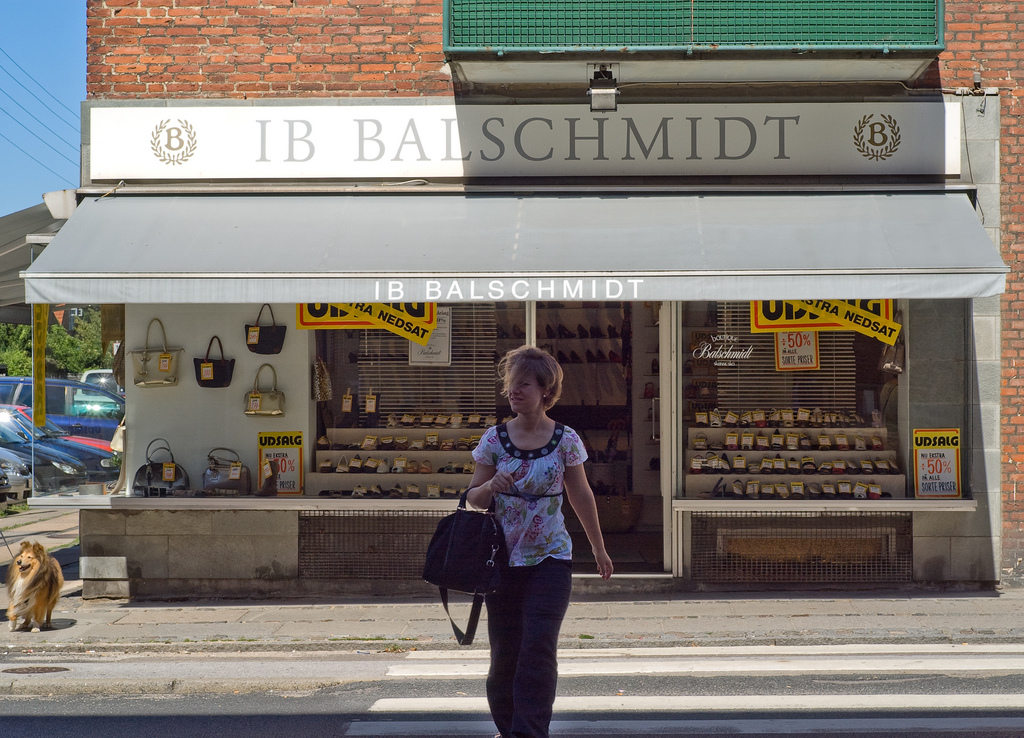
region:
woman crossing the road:
[425, 338, 628, 735]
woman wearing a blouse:
[456, 416, 606, 576]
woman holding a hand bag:
[424, 480, 510, 645]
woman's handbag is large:
[405, 479, 516, 658]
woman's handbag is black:
[405, 479, 522, 656]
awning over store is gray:
[14, 175, 1014, 308]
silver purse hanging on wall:
[120, 312, 191, 392]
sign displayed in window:
[904, 423, 965, 503]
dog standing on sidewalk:
[4, 530, 65, 641]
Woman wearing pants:
[454, 545, 587, 735]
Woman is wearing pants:
[457, 554, 578, 735]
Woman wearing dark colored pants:
[476, 555, 588, 734]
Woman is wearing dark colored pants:
[479, 550, 581, 734]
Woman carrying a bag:
[409, 471, 530, 650]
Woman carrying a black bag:
[411, 479, 517, 650]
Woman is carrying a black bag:
[408, 475, 516, 652]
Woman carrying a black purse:
[418, 476, 514, 647]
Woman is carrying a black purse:
[415, 472, 507, 651]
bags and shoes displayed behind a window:
[124, 305, 523, 498]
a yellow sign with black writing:
[909, 423, 963, 500]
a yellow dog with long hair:
[0, 536, 62, 631]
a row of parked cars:
[0, 371, 125, 512]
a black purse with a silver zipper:
[424, 486, 505, 645]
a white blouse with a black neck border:
[468, 422, 587, 563]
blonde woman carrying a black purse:
[421, 350, 609, 733]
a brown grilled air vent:
[295, 504, 455, 587]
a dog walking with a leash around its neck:
[1, 530, 65, 636]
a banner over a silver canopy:
[24, 97, 1007, 306]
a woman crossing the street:
[414, 344, 610, 734]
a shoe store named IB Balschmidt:
[78, 99, 1003, 612]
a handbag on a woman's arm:
[420, 488, 509, 647]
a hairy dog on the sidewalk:
[6, 542, 63, 632]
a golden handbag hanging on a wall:
[126, 315, 181, 386]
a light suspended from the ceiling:
[581, 61, 624, 118]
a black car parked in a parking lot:
[0, 403, 125, 489]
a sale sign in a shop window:
[912, 428, 967, 498]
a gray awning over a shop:
[31, 192, 1006, 300]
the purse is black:
[414, 485, 516, 654]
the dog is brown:
[3, 533, 76, 642]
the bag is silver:
[117, 314, 191, 406]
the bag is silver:
[240, 359, 292, 423]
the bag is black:
[183, 327, 244, 397]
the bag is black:
[234, 305, 296, 372]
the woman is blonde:
[454, 328, 598, 509]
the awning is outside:
[6, 192, 1019, 332]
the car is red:
[12, 397, 120, 456]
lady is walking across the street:
[465, 345, 617, 735]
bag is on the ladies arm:
[420, 483, 512, 646]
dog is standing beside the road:
[10, 540, 67, 632]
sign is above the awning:
[84, 94, 976, 186]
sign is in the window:
[910, 426, 962, 496]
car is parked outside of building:
[0, 423, 91, 485]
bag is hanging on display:
[128, 316, 185, 392]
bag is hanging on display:
[243, 364, 289, 413]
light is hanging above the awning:
[582, 57, 620, 118]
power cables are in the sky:
[0, 47, 80, 190]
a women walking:
[451, 333, 607, 733]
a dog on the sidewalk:
[9, 538, 67, 628]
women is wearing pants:
[480, 592, 569, 733]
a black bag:
[426, 513, 496, 596]